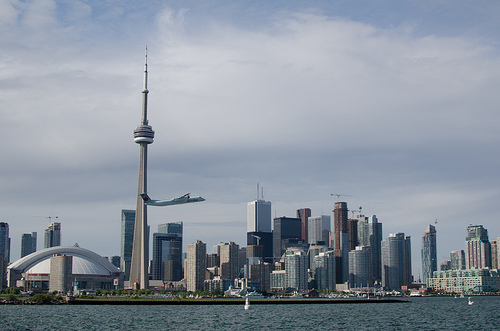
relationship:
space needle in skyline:
[128, 44, 154, 290] [0, 183, 499, 303]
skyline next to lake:
[0, 183, 499, 303] [0, 298, 499, 331]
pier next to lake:
[76, 299, 411, 305] [0, 298, 499, 331]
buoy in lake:
[242, 297, 249, 311] [0, 298, 499, 331]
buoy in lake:
[466, 295, 473, 306] [0, 298, 499, 331]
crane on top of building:
[330, 192, 356, 202] [331, 202, 350, 282]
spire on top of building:
[254, 182, 259, 200] [247, 200, 271, 233]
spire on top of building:
[260, 185, 265, 201] [247, 200, 271, 233]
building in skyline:
[6, 246, 121, 296] [0, 183, 499, 303]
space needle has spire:
[128, 44, 154, 290] [141, 43, 150, 126]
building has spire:
[247, 200, 271, 233] [254, 182, 259, 200]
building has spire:
[247, 200, 271, 233] [260, 185, 265, 201]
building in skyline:
[348, 245, 373, 289] [0, 183, 499, 303]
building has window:
[6, 246, 121, 296] [75, 280, 87, 289]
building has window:
[6, 246, 121, 296] [100, 281, 113, 289]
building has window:
[6, 246, 121, 296] [40, 280, 48, 294]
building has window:
[6, 246, 121, 296] [33, 280, 41, 295]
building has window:
[6, 246, 121, 296] [27, 279, 31, 293]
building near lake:
[6, 246, 121, 296] [0, 298, 499, 331]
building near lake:
[331, 202, 350, 282] [0, 298, 499, 331]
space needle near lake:
[128, 44, 154, 290] [0, 298, 499, 331]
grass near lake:
[73, 292, 195, 298] [0, 298, 499, 331]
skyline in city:
[0, 183, 499, 303] [2, 1, 498, 331]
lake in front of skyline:
[0, 298, 499, 331] [0, 183, 499, 303]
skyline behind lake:
[0, 183, 499, 303] [0, 298, 499, 331]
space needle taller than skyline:
[128, 44, 154, 290] [0, 183, 499, 303]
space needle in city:
[128, 44, 154, 290] [2, 1, 498, 331]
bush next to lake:
[6, 294, 22, 302] [0, 298, 499, 331]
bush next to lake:
[31, 293, 55, 303] [0, 298, 499, 331]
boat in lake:
[459, 293, 464, 299] [0, 298, 499, 331]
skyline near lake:
[0, 183, 499, 303] [0, 298, 499, 331]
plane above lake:
[136, 191, 206, 206] [0, 298, 499, 331]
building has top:
[121, 209, 136, 280] [121, 209, 135, 220]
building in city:
[348, 245, 373, 289] [2, 1, 498, 331]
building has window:
[428, 270, 500, 295] [438, 279, 441, 283]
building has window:
[428, 270, 500, 295] [453, 277, 458, 282]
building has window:
[428, 270, 500, 295] [431, 284, 434, 288]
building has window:
[428, 270, 500, 295] [475, 277, 480, 280]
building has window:
[428, 270, 500, 295] [445, 283, 449, 288]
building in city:
[331, 202, 350, 282] [2, 1, 498, 331]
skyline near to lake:
[0, 183, 499, 303] [0, 298, 499, 331]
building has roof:
[6, 246, 121, 296] [8, 245, 123, 275]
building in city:
[247, 200, 271, 233] [2, 1, 498, 331]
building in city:
[121, 209, 136, 280] [2, 1, 498, 331]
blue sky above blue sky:
[90, 0, 500, 31] [90, 0, 500, 31]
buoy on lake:
[242, 297, 249, 311] [0, 298, 499, 331]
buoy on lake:
[466, 295, 473, 306] [0, 298, 499, 331]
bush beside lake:
[6, 294, 22, 302] [0, 298, 499, 331]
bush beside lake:
[31, 293, 55, 303] [0, 298, 499, 331]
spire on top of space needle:
[141, 43, 150, 126] [128, 44, 154, 290]